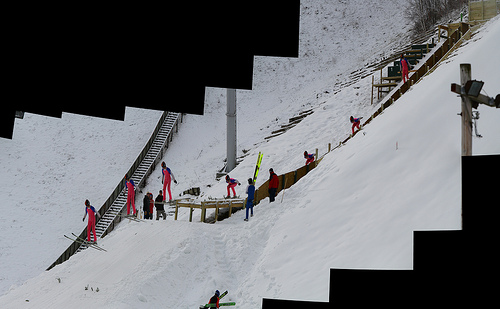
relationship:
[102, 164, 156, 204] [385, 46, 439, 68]
person in outfi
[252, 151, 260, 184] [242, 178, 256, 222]
pole held by person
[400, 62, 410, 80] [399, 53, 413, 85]
ski outfit worn by person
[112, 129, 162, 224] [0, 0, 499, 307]
tracks to take to hill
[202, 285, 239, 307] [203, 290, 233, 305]
skier carrying skis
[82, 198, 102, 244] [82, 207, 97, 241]
person in ski suit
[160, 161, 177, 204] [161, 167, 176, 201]
person in ski suit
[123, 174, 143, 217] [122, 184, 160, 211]
person in suit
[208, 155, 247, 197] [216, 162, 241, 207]
person in ski suite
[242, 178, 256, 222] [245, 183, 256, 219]
person in ski suit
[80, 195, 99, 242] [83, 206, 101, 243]
person in ski suit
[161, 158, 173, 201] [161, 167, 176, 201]
person in ski suit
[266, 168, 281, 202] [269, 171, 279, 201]
person in ski suit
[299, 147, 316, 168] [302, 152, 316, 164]
person in ski suit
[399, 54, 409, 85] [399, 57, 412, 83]
person in ski outfit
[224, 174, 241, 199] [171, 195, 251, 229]
person jumping off lift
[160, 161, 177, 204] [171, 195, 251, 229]
person jumping off lift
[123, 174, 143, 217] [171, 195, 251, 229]
person jumping off lift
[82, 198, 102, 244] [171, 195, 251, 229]
person jumping off lift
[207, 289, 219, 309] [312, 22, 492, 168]
skier walking up hill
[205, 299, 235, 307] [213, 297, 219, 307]
ski under arm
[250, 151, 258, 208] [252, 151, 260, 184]
pole with pole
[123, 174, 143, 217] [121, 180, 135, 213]
person in suit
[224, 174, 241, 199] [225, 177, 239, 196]
person in ski suite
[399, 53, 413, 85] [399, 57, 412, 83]
person in ski outfit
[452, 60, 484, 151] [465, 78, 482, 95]
pole with object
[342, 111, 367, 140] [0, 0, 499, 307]
skier coming down hill